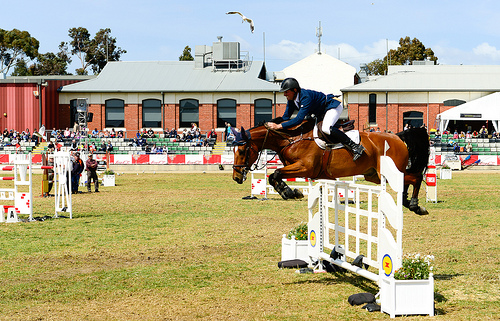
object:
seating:
[187, 147, 195, 150]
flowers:
[426, 266, 434, 270]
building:
[58, 41, 289, 139]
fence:
[280, 154, 435, 316]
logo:
[381, 254, 393, 278]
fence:
[251, 154, 357, 199]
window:
[141, 98, 165, 129]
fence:
[0, 150, 35, 220]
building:
[340, 64, 499, 134]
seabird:
[224, 10, 254, 33]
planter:
[378, 272, 434, 319]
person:
[85, 153, 102, 193]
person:
[267, 76, 367, 162]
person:
[72, 151, 83, 194]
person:
[206, 127, 218, 140]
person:
[139, 127, 149, 139]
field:
[1, 173, 499, 319]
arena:
[2, 127, 499, 319]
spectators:
[207, 129, 219, 138]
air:
[439, 0, 499, 64]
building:
[0, 75, 91, 140]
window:
[105, 98, 125, 127]